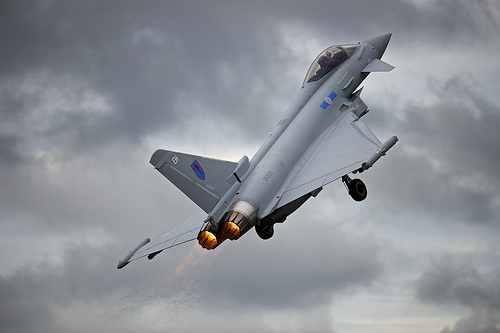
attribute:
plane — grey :
[113, 29, 401, 276]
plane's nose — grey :
[358, 27, 407, 55]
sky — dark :
[0, 1, 498, 331]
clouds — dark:
[51, 31, 148, 95]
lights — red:
[197, 221, 238, 248]